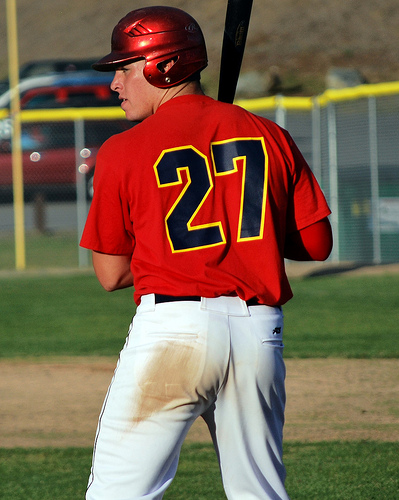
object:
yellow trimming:
[0, 81, 398, 123]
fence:
[2, 81, 399, 277]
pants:
[84, 293, 289, 500]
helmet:
[92, 6, 208, 89]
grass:
[281, 273, 398, 359]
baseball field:
[0, 0, 399, 500]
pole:
[5, 0, 26, 271]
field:
[0, 264, 398, 500]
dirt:
[132, 342, 219, 424]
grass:
[0, 443, 399, 500]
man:
[79, 6, 332, 500]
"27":
[154, 136, 268, 254]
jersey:
[79, 94, 333, 307]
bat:
[217, 0, 253, 104]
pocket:
[262, 339, 285, 380]